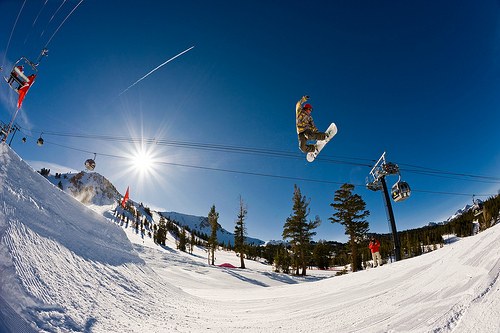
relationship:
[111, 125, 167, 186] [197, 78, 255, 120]
sun in sky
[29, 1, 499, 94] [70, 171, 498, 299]
blue sky at resort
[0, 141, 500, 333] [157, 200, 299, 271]
snow covered mountains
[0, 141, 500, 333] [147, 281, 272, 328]
snow covering ground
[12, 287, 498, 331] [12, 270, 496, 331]
snow covering ground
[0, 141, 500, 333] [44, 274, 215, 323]
snow covering ground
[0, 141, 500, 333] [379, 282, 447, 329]
snow covering ground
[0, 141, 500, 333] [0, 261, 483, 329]
snow covering ground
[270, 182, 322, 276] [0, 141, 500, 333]
tree on snow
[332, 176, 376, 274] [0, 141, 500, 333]
tree on snow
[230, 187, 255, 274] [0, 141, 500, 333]
tree on snow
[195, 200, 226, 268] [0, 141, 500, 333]
tree on snow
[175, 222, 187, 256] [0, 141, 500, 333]
tree on snow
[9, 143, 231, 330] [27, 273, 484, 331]
ramp covered in snow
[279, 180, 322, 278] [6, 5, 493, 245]
tree in distance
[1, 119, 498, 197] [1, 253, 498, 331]
cables run along snow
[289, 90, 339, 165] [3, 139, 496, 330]
skateboarder in half pipe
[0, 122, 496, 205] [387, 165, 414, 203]
ski lift has gondola